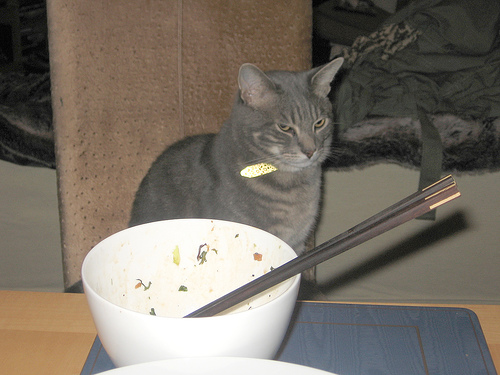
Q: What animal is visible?
A: A cat.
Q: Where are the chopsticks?
A: In the white bowl.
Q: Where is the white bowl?
A: On the blue placemat.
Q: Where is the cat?
A: Sitting on the chair.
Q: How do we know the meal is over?
A: The bowl is empty and dirty.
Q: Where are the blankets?
A: Behind the chair.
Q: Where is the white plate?
A: In front of the bowl.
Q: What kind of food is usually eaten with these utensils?
A: Asian food.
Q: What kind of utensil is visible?
A: Chopsticks.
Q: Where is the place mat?
A: On the table under the bowl.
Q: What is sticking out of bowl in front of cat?
A: Chopsticks.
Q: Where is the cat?
A: On the chair.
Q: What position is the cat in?
A: Sitting.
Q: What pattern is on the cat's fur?
A: Grey stripes.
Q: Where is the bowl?
A: On the table.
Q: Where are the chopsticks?
A: In the bowl.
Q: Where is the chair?
A: Behind the table.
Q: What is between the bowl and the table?
A: Placemat.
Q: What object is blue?
A: Placemat.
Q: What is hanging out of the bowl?
A: Chopsticks.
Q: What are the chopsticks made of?
A: Wood.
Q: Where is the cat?
A: On chair.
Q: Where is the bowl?
A: On blue mat.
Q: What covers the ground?
A: Carpet.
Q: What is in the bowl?
A: Food.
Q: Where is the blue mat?
A: On table.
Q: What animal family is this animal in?
A: Feline.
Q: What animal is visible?
A: Cat.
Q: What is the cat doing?
A: Sitting.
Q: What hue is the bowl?
A: White.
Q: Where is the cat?
A: Behind bowl.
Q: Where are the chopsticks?
A: In bowl.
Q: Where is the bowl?
A: On table.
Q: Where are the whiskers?
A: On cat.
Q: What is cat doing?
A: Staring.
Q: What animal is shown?
A: Cat.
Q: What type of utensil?
A: Chopstick.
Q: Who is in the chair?
A: Cat.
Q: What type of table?
A: Wood.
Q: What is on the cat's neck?
A: Collar.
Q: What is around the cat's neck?
A: A collar.